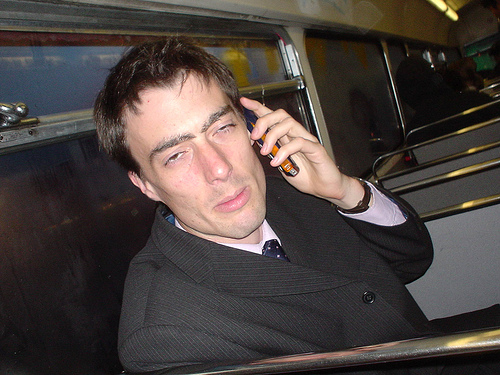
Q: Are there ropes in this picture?
A: No, there are no ropes.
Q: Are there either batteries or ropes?
A: No, there are no ropes or batteries.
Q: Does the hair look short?
A: Yes, the hair is short.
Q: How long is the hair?
A: The hair is short.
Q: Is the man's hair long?
A: No, the hair is short.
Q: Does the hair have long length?
A: No, the hair is short.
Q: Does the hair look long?
A: No, the hair is short.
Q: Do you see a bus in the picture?
A: Yes, there is a bus.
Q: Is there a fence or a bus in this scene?
A: Yes, there is a bus.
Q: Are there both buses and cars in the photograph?
A: No, there is a bus but no cars.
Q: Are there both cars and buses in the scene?
A: No, there is a bus but no cars.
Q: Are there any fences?
A: No, there are no fences.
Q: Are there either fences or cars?
A: No, there are no fences or cars.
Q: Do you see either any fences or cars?
A: No, there are no fences or cars.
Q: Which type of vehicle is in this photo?
A: The vehicle is a bus.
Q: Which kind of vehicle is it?
A: The vehicle is a bus.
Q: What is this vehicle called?
A: That is a bus.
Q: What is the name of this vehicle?
A: That is a bus.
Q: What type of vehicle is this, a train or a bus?
A: That is a bus.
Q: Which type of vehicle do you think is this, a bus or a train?
A: That is a bus.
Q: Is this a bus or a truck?
A: This is a bus.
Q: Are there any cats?
A: No, there are no cats.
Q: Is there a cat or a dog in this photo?
A: No, there are no cats or dogs.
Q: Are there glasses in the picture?
A: No, there are no glasses.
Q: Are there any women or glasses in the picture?
A: No, there are no glasses or women.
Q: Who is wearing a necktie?
A: The man is wearing a necktie.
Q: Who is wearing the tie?
A: The man is wearing a necktie.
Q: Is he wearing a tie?
A: Yes, the man is wearing a tie.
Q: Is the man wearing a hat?
A: No, the man is wearing a tie.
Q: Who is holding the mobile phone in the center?
A: The man is holding the cellphone.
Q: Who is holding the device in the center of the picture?
A: The man is holding the cellphone.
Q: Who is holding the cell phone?
A: The man is holding the cellphone.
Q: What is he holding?
A: The man is holding the mobile phone.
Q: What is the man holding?
A: The man is holding the mobile phone.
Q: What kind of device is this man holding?
A: The man is holding the mobile phone.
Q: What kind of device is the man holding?
A: The man is holding the mobile phone.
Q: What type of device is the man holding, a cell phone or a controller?
A: The man is holding a cell phone.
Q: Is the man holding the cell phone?
A: Yes, the man is holding the cell phone.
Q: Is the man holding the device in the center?
A: Yes, the man is holding the cell phone.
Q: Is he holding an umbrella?
A: No, the man is holding the cell phone.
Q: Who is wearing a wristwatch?
A: The man is wearing a wristwatch.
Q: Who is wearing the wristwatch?
A: The man is wearing a wristwatch.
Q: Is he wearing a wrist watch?
A: Yes, the man is wearing a wrist watch.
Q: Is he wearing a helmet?
A: No, the man is wearing a wrist watch.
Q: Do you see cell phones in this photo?
A: Yes, there is a cell phone.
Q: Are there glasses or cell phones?
A: Yes, there is a cell phone.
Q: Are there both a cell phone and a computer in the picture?
A: No, there is a cell phone but no computers.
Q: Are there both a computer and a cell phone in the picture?
A: No, there is a cell phone but no computers.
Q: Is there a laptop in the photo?
A: No, there are no laptops.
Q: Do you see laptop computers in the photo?
A: No, there are no laptop computers.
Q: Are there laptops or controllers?
A: No, there are no laptops or controllers.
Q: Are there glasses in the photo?
A: No, there are no glasses.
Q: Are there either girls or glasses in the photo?
A: No, there are no glasses or girls.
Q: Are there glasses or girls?
A: No, there are no glasses or girls.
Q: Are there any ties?
A: Yes, there is a tie.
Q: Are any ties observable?
A: Yes, there is a tie.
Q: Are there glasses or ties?
A: Yes, there is a tie.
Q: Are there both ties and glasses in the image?
A: No, there is a tie but no glasses.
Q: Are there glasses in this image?
A: No, there are no glasses.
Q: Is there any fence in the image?
A: No, there are no fences.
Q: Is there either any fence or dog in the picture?
A: No, there are no fences or dogs.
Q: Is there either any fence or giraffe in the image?
A: No, there are no fences or giraffes.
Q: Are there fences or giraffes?
A: No, there are no fences or giraffes.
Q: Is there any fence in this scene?
A: No, there are no fences.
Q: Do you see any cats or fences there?
A: No, there are no fences or cats.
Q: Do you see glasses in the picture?
A: No, there are no glasses.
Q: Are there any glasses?
A: No, there are no glasses.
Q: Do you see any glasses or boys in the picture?
A: No, there are no glasses or boys.